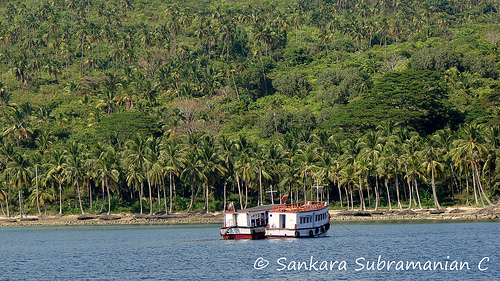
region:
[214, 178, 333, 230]
steam boat on the water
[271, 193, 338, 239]
steam boat on the water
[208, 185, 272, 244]
steam boat on the water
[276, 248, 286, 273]
white print style letter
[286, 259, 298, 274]
white print style letter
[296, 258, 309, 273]
white print style letter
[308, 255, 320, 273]
white print style letter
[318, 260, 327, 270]
white print style letter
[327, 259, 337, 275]
white print style letter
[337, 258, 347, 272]
white print style letter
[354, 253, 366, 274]
white print style letter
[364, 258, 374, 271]
white print style letter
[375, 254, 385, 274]
white print style letter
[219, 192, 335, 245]
two boats in the water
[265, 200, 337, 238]
white boat with red trim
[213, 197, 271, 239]
white boat with dark red trim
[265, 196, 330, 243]
boat with orange railings on top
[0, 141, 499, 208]
line of palm trees on shore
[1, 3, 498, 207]
jungle of vegetation on shore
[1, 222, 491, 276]
calm blue ocean water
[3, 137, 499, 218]
beach covered in palm trees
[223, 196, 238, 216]
flag flying on white boat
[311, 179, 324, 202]
cross on front of white boat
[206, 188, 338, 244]
boats on the water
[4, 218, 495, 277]
water of ocean or lake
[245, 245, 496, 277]
watermark of person taking the photo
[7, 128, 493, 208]
palm trees on the shore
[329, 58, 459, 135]
deciduous trees growing on hillside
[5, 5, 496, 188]
hill near the water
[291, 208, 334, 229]
passenger windows on the side of the boat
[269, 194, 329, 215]
red roof of boat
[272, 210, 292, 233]
open back door of boat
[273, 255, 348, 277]
first name of person that owns rights to photo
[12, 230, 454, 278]
ripples on the water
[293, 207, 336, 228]
windows on the boat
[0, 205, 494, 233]
sand on the beach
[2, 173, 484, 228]
trunks of the trees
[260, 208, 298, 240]
back of the boat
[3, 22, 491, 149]
hill by the shore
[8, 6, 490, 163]
trees on the hill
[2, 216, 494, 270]
water by the shore